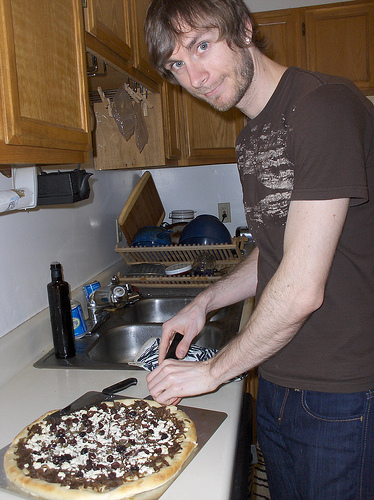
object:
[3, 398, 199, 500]
pizza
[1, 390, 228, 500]
tray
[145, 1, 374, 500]
man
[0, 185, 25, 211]
dispenser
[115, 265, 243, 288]
strainer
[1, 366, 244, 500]
counter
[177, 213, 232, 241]
bowl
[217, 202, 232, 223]
outlet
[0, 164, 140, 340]
wall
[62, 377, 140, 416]
knife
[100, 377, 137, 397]
handle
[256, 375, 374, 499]
jeans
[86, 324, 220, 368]
sink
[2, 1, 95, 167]
cabinets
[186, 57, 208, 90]
nose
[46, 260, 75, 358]
bottle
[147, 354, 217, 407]
hand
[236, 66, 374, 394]
shirt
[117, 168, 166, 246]
cutting-board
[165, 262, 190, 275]
lid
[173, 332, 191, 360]
thumb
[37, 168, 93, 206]
kettle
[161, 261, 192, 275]
dishes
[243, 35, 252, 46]
earing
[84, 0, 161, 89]
cabinet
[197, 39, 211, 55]
eyes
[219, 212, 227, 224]
plug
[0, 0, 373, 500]
kitchen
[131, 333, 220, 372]
towel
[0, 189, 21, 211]
towel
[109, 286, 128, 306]
faucet